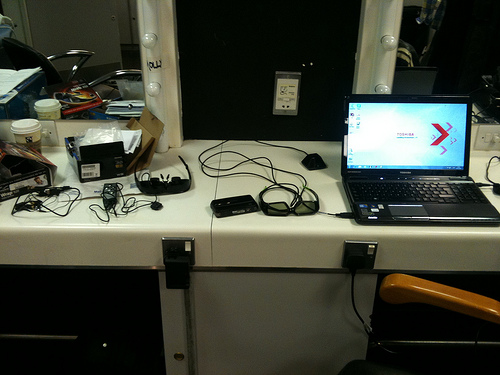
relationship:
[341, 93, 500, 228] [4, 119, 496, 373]
computer sitting on table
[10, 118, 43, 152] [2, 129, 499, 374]
coffee cup sitting on desk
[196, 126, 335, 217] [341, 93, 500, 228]
cord connected to computer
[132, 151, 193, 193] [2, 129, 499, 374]
glasses sitting on desk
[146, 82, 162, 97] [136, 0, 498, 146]
bulb attached to wall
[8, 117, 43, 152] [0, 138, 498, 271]
coffee cup on counter top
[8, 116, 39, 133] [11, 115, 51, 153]
lid on coffee cup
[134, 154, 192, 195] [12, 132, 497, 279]
glasses sitting on table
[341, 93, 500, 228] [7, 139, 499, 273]
computer sitting on counter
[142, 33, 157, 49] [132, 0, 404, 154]
bulb coming out of wall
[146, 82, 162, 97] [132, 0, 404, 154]
bulb coming out of wall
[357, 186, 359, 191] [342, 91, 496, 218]
button on computer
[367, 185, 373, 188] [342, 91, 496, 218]
button on computer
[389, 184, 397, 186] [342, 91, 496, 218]
button on computer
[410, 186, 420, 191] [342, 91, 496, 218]
button on computer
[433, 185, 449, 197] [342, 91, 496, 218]
button on computer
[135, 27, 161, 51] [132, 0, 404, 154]
bulb on wall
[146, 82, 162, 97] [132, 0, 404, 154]
bulb on wall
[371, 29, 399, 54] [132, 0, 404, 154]
bulb on wall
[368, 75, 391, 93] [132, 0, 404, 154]
bulb on wall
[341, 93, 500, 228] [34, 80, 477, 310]
computer on table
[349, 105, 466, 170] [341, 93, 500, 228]
glowing image on computer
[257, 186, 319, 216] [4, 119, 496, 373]
sunglasses on table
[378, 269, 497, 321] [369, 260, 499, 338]
arm of chair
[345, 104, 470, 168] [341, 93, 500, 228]
screen on computer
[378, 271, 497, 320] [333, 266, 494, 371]
arm on chair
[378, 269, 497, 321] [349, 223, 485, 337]
arm of chair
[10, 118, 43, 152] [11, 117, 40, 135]
coffee cup with lid